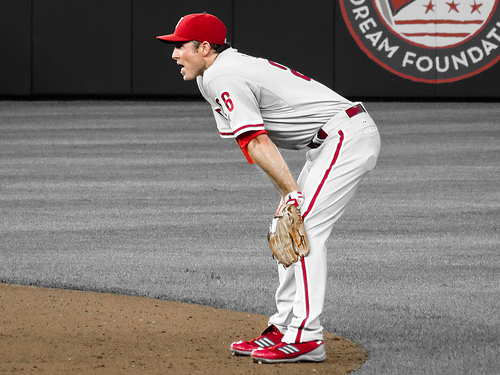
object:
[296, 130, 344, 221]
red stripe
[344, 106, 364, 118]
red belt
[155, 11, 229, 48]
cap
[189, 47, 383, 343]
uniform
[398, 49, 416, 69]
letter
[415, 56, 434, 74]
letter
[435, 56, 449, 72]
letter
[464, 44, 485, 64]
letter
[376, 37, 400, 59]
letter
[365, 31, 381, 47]
letter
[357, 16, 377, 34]
letter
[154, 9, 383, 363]
man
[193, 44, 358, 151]
jersey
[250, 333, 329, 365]
shoe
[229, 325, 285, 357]
shoe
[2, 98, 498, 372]
field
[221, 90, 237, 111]
number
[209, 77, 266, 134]
sleeve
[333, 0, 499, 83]
logo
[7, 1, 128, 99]
wall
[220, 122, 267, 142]
stripes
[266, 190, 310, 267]
glove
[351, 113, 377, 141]
pocket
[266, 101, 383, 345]
pants